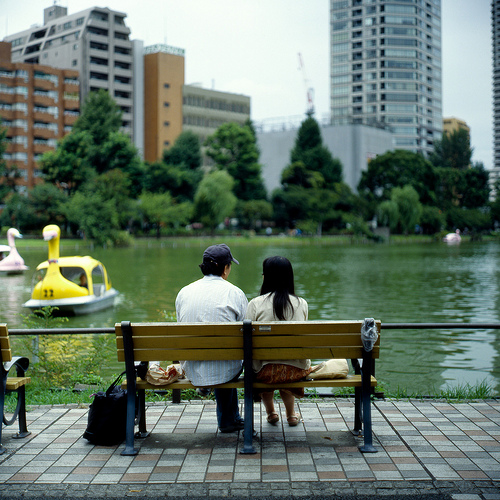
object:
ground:
[7, 396, 499, 495]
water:
[12, 243, 496, 402]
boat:
[21, 222, 119, 316]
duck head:
[40, 223, 60, 243]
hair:
[264, 252, 287, 275]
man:
[174, 243, 250, 433]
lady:
[246, 257, 310, 426]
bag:
[83, 384, 138, 446]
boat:
[0, 228, 29, 275]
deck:
[0, 376, 499, 499]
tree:
[266, 109, 376, 230]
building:
[0, 0, 253, 213]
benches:
[115, 320, 382, 456]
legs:
[259, 384, 278, 411]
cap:
[203, 244, 241, 266]